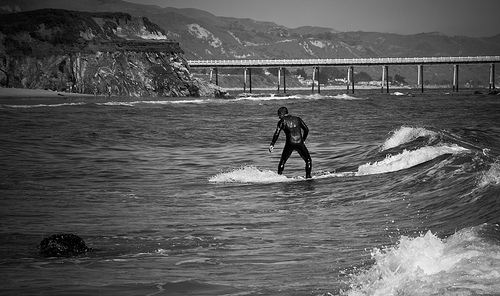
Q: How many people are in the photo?
A: One.